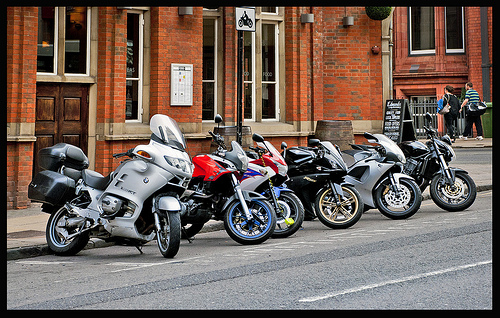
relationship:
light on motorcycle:
[163, 152, 198, 179] [30, 105, 196, 256]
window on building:
[255, 17, 285, 120] [161, 13, 351, 140]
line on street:
[298, 257, 496, 308] [5, 194, 496, 314]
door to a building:
[36, 82, 88, 192] [394, 6, 491, 140]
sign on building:
[157, 57, 193, 113] [67, 15, 358, 115]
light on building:
[234, 142, 286, 192] [29, 21, 485, 272]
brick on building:
[318, 9, 377, 119] [8, 2, 389, 210]